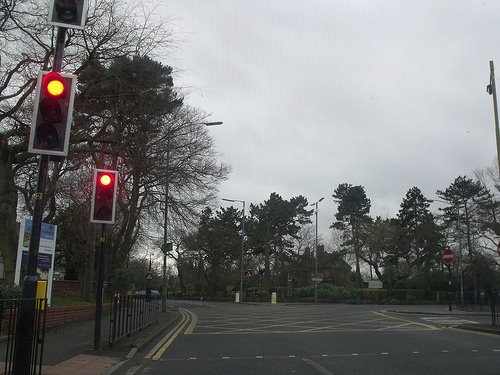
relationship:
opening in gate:
[128, 300, 133, 341] [103, 287, 173, 328]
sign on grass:
[15, 214, 57, 308] [2, 281, 82, 303]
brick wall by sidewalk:
[24, 305, 126, 330] [33, 296, 146, 371]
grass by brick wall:
[48, 291, 91, 311] [31, 298, 111, 330]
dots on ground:
[152, 346, 476, 363] [174, 329, 498, 369]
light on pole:
[204, 120, 229, 128] [135, 104, 240, 329]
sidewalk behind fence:
[20, 296, 166, 369] [98, 268, 161, 348]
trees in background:
[241, 189, 311, 296] [13, 107, 499, 319]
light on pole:
[92, 168, 115, 219] [94, 220, 110, 350]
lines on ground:
[186, 315, 466, 342] [132, 294, 499, 371]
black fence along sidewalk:
[2, 292, 159, 373] [0, 297, 160, 374]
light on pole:
[28, 73, 76, 156] [9, 161, 57, 365]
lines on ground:
[181, 299, 441, 334] [195, 315, 488, 369]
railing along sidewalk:
[108, 295, 158, 345] [53, 325, 92, 352]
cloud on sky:
[321, 36, 411, 103] [277, 59, 399, 138]